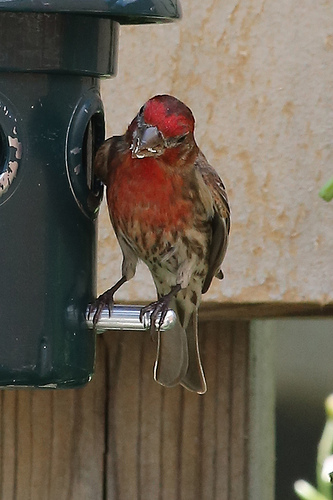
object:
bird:
[84, 94, 228, 393]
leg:
[84, 248, 139, 329]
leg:
[137, 249, 199, 337]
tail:
[150, 264, 208, 397]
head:
[124, 93, 202, 170]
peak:
[129, 115, 172, 162]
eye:
[135, 105, 149, 120]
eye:
[176, 131, 188, 146]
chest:
[110, 137, 199, 277]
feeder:
[0, 1, 182, 389]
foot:
[81, 274, 130, 336]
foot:
[140, 282, 181, 342]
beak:
[130, 112, 179, 164]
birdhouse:
[1, 2, 177, 389]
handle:
[87, 307, 178, 333]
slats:
[4, 323, 252, 499]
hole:
[0, 127, 7, 178]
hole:
[81, 112, 107, 196]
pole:
[87, 305, 176, 330]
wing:
[95, 135, 117, 187]